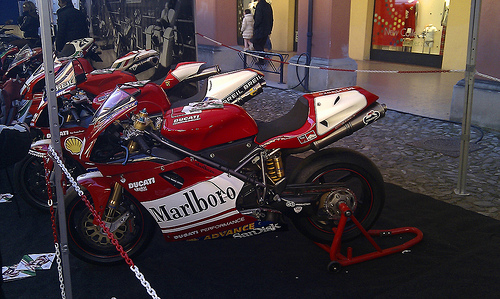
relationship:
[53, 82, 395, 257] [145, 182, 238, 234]
motorcycle with marlboro logo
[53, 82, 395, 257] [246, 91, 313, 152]
motorcycle has a seat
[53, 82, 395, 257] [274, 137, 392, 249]
motorcycle has a wheel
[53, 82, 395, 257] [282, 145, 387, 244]
motorcycle has a wheel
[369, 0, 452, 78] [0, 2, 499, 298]
window display in mall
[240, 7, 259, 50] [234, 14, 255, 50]
person wearing white clothes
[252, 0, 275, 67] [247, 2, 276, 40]
person wearing a black coat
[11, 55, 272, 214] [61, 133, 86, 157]
motorcycle has a shell logo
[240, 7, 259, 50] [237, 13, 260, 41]
person in white coat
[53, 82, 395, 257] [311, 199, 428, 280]
motorcycle on a bike stand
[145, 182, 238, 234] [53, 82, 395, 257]
marlboro logo on motorcycle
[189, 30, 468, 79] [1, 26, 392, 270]
chain around motorcycles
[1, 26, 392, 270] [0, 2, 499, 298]
motorcycles in mall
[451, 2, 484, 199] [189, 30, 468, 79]
pole holding chain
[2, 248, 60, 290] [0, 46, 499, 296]
booklets are on ground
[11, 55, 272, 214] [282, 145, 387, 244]
motorcycle has a wheel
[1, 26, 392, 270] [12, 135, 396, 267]
motorcycles have wheels